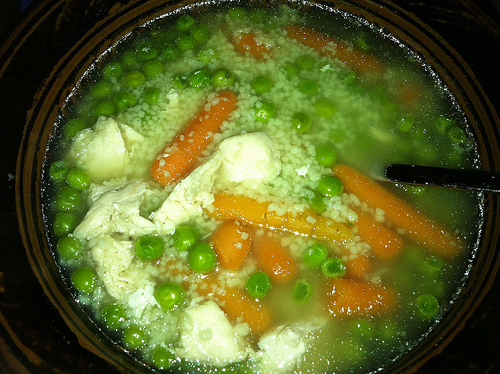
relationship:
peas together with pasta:
[62, 167, 117, 303] [84, 62, 447, 368]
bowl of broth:
[1, 1, 498, 371] [47, 8, 479, 371]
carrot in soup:
[151, 89, 239, 186] [96, 62, 446, 340]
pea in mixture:
[244, 264, 279, 306] [92, 55, 438, 347]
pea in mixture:
[188, 245, 216, 271] [43, 2, 485, 369]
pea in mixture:
[155, 283, 185, 307] [43, 2, 485, 369]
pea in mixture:
[318, 172, 346, 196] [43, 2, 485, 369]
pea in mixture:
[313, 142, 336, 163] [43, 2, 485, 369]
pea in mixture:
[66, 166, 88, 190] [43, 2, 485, 369]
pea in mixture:
[118, 70, 146, 95] [68, 84, 445, 325]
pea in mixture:
[146, 343, 176, 370] [92, 55, 438, 347]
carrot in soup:
[203, 221, 263, 270] [95, 50, 438, 326]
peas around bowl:
[49, 165, 124, 299] [11, 5, 499, 324]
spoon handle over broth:
[373, 162, 498, 193] [47, 8, 479, 371]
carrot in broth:
[151, 89, 239, 186] [45, 5, 492, 364]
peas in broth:
[307, 244, 324, 264] [47, 8, 479, 371]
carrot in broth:
[156, 89, 240, 177] [47, 8, 479, 371]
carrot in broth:
[203, 221, 263, 270] [47, 8, 479, 371]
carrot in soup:
[338, 179, 433, 244] [90, 85, 372, 312]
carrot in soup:
[243, 200, 344, 253] [90, 85, 372, 312]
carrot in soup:
[316, 279, 399, 305] [90, 85, 372, 312]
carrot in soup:
[151, 89, 239, 186] [90, 85, 372, 312]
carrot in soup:
[203, 226, 263, 268] [90, 85, 372, 312]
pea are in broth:
[152, 282, 186, 310] [47, 8, 479, 371]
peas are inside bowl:
[187, 43, 343, 166] [1, 1, 498, 371]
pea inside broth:
[318, 174, 345, 196] [47, 8, 479, 371]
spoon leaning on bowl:
[382, 163, 499, 193] [1, 1, 498, 371]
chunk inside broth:
[65, 114, 137, 178] [47, 8, 479, 371]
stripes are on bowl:
[4, 6, 106, 372] [1, 1, 498, 371]